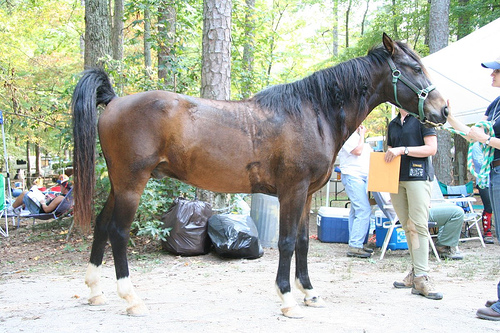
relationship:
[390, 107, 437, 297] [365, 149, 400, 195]
person on envelope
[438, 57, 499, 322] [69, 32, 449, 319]
girl on brown horse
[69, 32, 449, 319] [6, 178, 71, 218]
brown horse near people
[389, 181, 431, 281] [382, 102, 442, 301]
pants on woman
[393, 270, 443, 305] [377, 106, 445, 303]
shoes on person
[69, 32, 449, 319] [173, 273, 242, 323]
brown horse on ground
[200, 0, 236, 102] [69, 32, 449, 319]
tree trunk behind brown horse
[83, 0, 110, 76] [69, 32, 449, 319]
tree trunk behind brown horse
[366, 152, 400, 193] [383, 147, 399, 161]
envelope in hands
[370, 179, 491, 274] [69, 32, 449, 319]
chairs near brown horse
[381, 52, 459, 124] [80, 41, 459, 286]
bridle on horse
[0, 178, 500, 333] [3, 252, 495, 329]
ground of ground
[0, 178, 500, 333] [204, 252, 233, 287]
ground of ground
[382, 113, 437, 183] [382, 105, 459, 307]
shirt on woman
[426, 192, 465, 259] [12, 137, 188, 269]
person sitting in park area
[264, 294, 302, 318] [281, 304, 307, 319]
part of hoof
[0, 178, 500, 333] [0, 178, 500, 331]
ground of ground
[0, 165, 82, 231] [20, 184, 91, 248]
person sitting in chair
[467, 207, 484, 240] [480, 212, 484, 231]
sock with dots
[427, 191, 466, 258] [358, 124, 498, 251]
man reading in chair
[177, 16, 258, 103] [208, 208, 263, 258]
trunk behind trash bag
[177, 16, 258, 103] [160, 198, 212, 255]
trunk behind trash bag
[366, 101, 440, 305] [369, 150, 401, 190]
man holding envelope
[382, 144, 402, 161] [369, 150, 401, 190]
hand holding envelope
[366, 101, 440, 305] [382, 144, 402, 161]
man has hand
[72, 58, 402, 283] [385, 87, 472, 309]
brown horse standing by woman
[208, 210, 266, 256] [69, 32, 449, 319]
trash bag behind brown horse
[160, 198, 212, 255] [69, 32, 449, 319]
trash bag behind brown horse